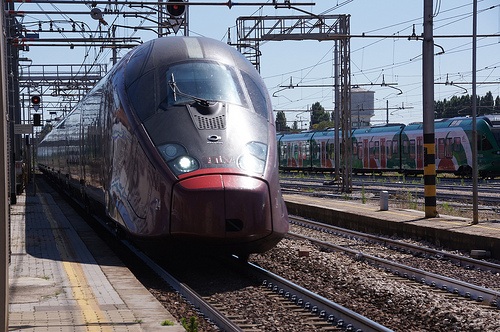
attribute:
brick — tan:
[56, 285, 68, 301]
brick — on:
[41, 295, 48, 307]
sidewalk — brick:
[3, 180, 187, 329]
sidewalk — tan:
[15, 176, 163, 326]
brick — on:
[102, 296, 129, 319]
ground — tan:
[291, 92, 323, 159]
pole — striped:
[423, 0, 437, 218]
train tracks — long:
[279, 214, 499, 302]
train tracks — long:
[39, 172, 399, 330]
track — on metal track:
[192, 276, 320, 308]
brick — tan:
[28, 304, 52, 323]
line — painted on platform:
[33, 175, 108, 330]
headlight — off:
[176, 157, 192, 169]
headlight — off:
[236, 155, 256, 170]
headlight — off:
[161, 142, 176, 157]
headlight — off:
[248, 143, 261, 155]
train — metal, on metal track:
[26, 33, 291, 260]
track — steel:
[172, 260, 355, 330]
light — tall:
[30, 91, 42, 115]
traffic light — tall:
[31, 92, 42, 105]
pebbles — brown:
[140, 211, 499, 326]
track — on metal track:
[322, 265, 344, 283]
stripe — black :
[424, 132, 434, 144]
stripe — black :
[422, 154, 433, 164]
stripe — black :
[423, 175, 438, 188]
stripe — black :
[422, 193, 439, 207]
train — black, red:
[29, 27, 300, 271]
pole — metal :
[411, 0, 448, 210]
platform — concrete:
[39, 203, 466, 219]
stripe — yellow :
[30, 177, 110, 329]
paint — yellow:
[73, 283, 93, 310]